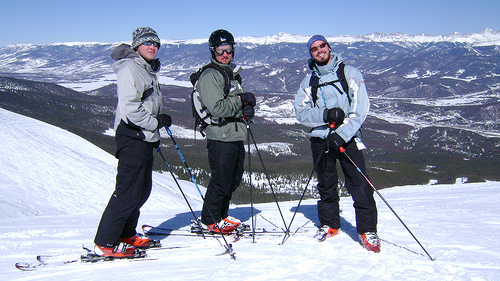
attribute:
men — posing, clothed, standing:
[91, 18, 389, 259]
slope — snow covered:
[1, 108, 500, 278]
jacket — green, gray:
[191, 57, 253, 142]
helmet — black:
[205, 27, 234, 45]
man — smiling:
[291, 33, 391, 257]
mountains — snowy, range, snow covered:
[3, 25, 499, 94]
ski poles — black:
[275, 118, 435, 258]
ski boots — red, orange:
[198, 215, 244, 237]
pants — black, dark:
[200, 139, 253, 222]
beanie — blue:
[306, 30, 331, 47]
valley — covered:
[2, 73, 498, 190]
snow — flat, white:
[136, 250, 443, 271]